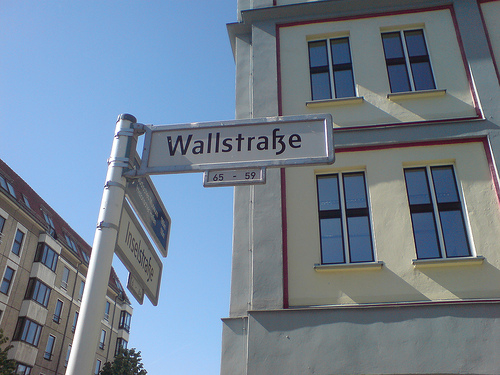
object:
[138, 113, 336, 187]
silver border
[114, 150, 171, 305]
sign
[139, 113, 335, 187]
sign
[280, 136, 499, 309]
red trim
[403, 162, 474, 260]
window section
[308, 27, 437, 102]
window section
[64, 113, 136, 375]
post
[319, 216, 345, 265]
window pane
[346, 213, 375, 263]
window pane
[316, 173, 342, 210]
window pane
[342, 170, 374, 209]
window pane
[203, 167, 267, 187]
numbers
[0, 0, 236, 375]
sky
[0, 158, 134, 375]
buildings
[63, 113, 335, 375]
sign post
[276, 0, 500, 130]
red trim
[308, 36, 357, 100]
window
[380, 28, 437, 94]
window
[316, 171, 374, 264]
window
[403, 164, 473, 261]
window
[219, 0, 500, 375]
building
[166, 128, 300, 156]
black writing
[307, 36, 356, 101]
window frame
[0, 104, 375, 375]
street corner